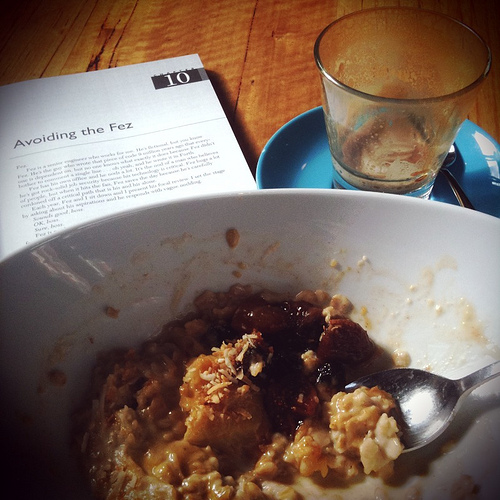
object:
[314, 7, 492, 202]
glass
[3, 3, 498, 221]
table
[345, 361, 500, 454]
spoon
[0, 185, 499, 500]
bowl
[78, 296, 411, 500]
porridge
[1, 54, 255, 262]
paper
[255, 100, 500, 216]
plate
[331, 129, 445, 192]
water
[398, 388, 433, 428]
light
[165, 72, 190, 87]
number 10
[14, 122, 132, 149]
avoiding the fez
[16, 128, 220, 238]
text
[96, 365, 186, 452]
crumbs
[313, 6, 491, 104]
lip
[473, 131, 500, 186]
reflection